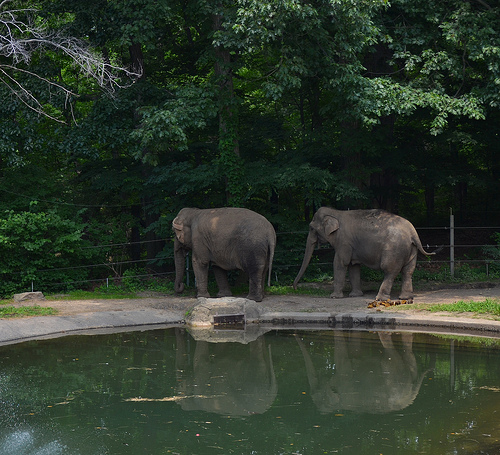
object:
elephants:
[172, 206, 276, 302]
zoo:
[1, 1, 500, 452]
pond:
[0, 329, 500, 454]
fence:
[13, 207, 500, 292]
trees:
[1, 0, 498, 296]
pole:
[450, 215, 455, 277]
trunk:
[174, 236, 186, 292]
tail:
[267, 243, 277, 288]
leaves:
[127, 77, 246, 166]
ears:
[323, 216, 339, 236]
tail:
[413, 235, 443, 256]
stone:
[13, 291, 46, 301]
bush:
[0, 201, 93, 298]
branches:
[0, 1, 143, 127]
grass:
[429, 298, 498, 313]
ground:
[0, 212, 499, 341]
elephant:
[292, 206, 443, 300]